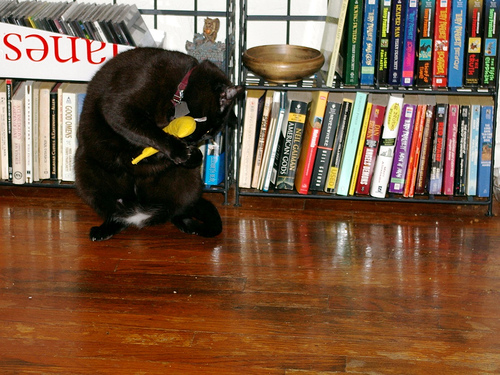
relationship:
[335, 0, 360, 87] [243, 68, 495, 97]
book on top of shelf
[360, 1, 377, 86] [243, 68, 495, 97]
book on top of shelf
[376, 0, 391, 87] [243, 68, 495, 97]
book on top of shelf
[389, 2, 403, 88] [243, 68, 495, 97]
book on top of shelf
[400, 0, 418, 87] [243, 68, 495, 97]
book on top of shelf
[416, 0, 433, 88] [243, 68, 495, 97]
book on top of shelf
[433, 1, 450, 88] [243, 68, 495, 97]
book on top of shelf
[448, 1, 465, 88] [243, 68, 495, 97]
book on top of shelf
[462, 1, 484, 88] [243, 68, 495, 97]
book on top of shelf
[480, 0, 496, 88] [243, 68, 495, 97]
book on top of shelf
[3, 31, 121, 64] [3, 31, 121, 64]
lettering printed on lettering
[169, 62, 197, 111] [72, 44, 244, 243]
collar around cat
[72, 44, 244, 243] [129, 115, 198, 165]
cat playing with toy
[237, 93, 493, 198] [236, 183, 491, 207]
books on top of shelf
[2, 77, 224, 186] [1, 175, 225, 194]
books on top of shelf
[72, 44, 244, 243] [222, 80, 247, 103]
cat has ear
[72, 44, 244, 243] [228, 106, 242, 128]
cat has ear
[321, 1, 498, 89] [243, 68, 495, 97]
books on top of shelf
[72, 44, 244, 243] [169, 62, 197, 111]
cat wearing collar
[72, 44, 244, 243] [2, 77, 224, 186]
cat in front of books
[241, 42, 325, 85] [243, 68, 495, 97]
dish on top of shelf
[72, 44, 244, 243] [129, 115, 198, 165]
cat gripping toy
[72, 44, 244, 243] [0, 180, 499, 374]
cat standing on floor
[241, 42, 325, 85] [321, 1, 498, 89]
dish next to books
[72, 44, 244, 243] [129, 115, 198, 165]
cat holding toy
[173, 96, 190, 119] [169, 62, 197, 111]
tag hanging from collar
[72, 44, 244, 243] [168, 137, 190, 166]
cat has paw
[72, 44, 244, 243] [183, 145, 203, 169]
cat has paw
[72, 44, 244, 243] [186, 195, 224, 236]
cat has tail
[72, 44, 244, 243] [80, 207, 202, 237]
cat standing on legs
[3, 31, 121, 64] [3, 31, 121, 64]
lettering has lettering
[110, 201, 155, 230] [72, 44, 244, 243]
patch on bottom of cat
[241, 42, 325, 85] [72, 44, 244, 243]
dish behind cat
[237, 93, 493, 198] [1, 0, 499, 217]
books on top of shelves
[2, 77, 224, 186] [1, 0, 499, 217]
books on top of shelves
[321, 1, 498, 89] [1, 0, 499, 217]
books on top of shelves